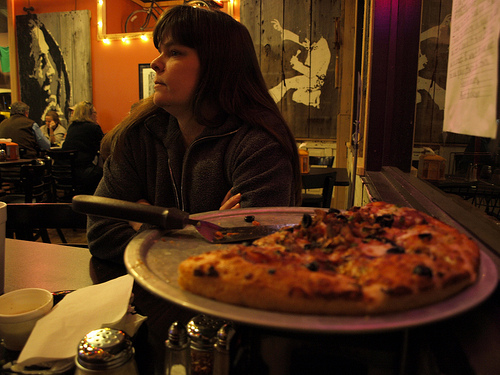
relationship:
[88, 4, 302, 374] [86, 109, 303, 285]
lady wearing coat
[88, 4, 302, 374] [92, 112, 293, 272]
lady in a coat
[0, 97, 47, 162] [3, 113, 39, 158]
man in a vest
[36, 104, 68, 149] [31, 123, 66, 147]
woman in a jacket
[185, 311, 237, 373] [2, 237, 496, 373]
pepper on table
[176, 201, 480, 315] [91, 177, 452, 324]
pizza on a pan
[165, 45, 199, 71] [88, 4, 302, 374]
eye of a lady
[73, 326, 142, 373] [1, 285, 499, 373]
salt shaker on a table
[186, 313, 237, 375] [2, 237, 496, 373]
pepper on a table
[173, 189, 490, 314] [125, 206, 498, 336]
pizza on a pan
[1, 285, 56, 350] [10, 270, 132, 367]
cup near napkin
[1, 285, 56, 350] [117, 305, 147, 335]
cup near napkin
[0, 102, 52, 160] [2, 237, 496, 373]
man sitting at table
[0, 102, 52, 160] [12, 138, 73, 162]
man sitting at table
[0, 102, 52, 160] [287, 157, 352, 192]
man sitting at table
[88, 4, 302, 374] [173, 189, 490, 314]
lady in front of pizza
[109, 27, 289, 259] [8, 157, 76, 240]
lady sitting on chair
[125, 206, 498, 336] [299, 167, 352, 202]
pan sitting on table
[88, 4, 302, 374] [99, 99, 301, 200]
lady wearing jacket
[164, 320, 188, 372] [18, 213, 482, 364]
salt shaker sitting on table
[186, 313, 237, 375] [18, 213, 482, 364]
pepper sitting on table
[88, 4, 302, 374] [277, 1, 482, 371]
lady sitting in restaurant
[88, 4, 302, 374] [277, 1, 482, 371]
lady eating in a restaurant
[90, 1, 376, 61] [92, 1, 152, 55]
lights highlighting art work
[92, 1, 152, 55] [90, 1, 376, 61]
art work displayed by lights